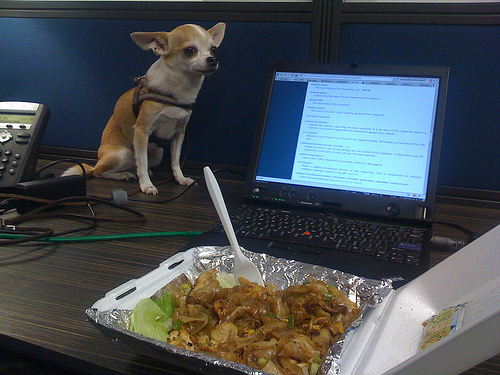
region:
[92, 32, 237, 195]
this is a dog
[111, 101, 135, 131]
the dog is brown in color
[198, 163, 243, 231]
this is a fox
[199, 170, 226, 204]
the fox is white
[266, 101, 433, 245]
this is a laptop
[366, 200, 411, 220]
the laptop is black in color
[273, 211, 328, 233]
these are the buttons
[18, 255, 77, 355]
this is a table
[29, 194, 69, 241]
this is a cable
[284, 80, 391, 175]
this is the screen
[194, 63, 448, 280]
inside of open laptop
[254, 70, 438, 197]
glowing image on screen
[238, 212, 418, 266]
buttons on computer keyboard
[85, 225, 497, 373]
open container of food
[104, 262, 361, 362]
food on tin foil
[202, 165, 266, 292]
white utensil standing up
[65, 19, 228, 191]
dog sitting on table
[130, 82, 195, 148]
harness on dog body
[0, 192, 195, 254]
tangle of electrical wires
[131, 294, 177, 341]
green lettuce in container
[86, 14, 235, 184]
dog on the desk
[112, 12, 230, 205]
cute dog on the desk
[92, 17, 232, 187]
adorable dog on the desk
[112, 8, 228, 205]
little dog on the desk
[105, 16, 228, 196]
small dog on the desk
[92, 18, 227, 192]
miniature dog on the desk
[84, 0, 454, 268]
dog and computer on the desk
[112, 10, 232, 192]
alert dog on the desk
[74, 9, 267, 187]
calm dog on the desk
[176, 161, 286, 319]
plastic fork in food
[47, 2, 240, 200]
The dog is sitting on a table.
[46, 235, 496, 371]
An open box of food.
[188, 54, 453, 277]
The laptop is black.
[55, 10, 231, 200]
The little dog is a chiuahua.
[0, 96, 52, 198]
An electronic device on the table.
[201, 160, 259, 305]
A plastic fork sticking out of the food.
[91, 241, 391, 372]
Tinfoil is under the food.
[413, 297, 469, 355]
A sauce packet in the lid of the box.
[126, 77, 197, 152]
The dog is wearing a harness.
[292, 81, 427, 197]
Text is on the computer screen.